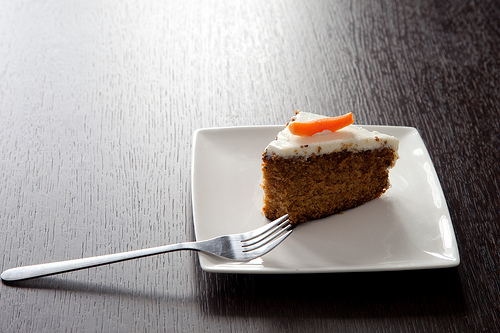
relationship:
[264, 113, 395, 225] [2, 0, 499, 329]
cake on top of table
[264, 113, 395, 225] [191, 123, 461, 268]
cake on top of plate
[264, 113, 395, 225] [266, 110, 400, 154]
cake with icing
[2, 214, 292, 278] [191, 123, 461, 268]
fork on top of plate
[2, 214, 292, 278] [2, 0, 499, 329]
fork on top of table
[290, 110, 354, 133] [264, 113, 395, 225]
carrot on top of cake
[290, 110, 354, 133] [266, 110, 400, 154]
carrot on top of icing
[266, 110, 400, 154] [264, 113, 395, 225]
icing on top of cake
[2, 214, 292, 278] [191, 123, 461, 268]
fork leaning on plate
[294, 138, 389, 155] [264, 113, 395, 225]
crumbs from cake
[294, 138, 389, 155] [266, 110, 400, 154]
crumbs on side of icing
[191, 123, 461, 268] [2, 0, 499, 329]
plate on top of table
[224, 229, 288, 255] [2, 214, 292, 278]
light reflecting off fork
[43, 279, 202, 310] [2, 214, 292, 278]
shadow of fork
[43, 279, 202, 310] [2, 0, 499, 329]
shadow on top of table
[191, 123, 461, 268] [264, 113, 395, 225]
plate with cake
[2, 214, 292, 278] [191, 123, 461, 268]
fork resting on plate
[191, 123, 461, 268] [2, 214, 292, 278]
plate with fork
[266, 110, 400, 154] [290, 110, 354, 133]
icing with carrot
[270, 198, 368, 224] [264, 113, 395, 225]
crust at bottom of cake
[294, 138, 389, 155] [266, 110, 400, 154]
crumbs on edge of icing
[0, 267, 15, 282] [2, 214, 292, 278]
edge of fork